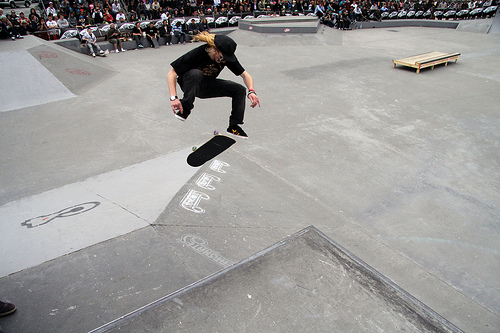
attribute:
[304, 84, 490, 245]
concrete — light, brown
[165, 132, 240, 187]
skateboard — black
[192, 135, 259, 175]
skateboard — black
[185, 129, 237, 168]
skateboard — in mid air, black, flipped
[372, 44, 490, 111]
platform — wooden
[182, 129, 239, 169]
skateboard — Black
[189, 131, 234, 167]
skate board — Black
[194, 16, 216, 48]
hair — blonde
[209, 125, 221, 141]
wheels — white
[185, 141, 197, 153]
wheels — white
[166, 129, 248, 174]
skateboard — black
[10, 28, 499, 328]
floor — tarmacked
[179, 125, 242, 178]
skateboard — Black 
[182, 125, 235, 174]
skateboard — Black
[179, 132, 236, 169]
skate board — Black 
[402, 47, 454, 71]
rail — brown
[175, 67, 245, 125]
pants — black